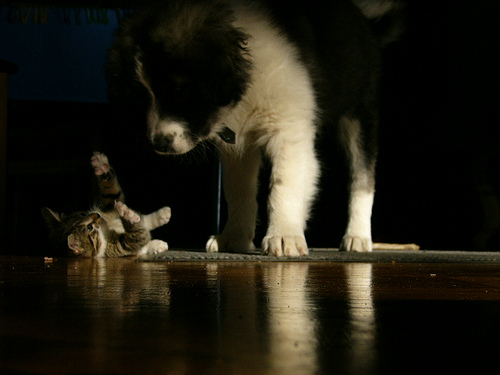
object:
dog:
[124, 5, 461, 251]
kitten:
[41, 147, 175, 274]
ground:
[2, 246, 474, 371]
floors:
[0, 247, 484, 363]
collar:
[214, 123, 240, 147]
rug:
[149, 248, 482, 274]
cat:
[40, 151, 174, 259]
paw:
[259, 229, 311, 259]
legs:
[87, 149, 150, 259]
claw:
[112, 200, 141, 223]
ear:
[42, 205, 60, 227]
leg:
[260, 103, 322, 258]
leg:
[339, 101, 381, 253]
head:
[132, 1, 246, 157]